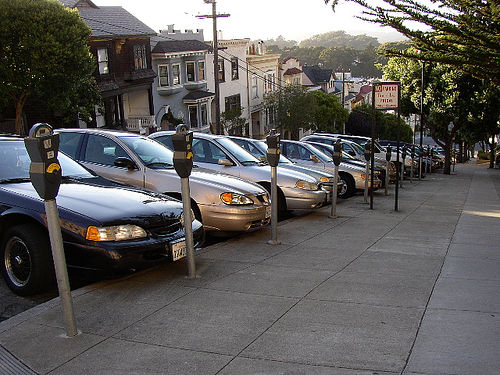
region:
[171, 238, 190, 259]
white licence plate on a black car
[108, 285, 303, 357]
concrete sidewalk square next to sidewalk square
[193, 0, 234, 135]
tall wooden utility pole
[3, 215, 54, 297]
black rubber tire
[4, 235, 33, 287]
chrome hubcap surrounded by tire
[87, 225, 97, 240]
yellow turn signal light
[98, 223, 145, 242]
white headlight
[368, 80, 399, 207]
white sign on metal pole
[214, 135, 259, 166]
windshield on front of car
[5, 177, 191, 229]
metal hood of car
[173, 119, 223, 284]
parking meter on sidewalk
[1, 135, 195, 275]
black car parked on street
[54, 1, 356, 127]
row of houses by street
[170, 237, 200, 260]
license plate on front of car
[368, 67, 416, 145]
no parking sign on sidewalk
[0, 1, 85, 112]
tree across the street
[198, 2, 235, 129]
light pole across the street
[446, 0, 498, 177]
row of trees down the sidewalk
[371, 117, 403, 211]
pole holding no parking sign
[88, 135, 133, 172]
passenger window of car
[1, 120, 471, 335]
A long row of parking meters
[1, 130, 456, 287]
A long row of parked cars in a parking lot.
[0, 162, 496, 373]
Cemented, clean sidewalk.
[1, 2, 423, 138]
A long row of houses behind the parked cars.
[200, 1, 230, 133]
Elecricity pole supporting overhead wires.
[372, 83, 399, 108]
A signboard on the sidewalk.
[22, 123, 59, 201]
A parking meter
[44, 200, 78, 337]
A metal pole on which a parking meter is mounted.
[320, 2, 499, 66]
A tree with long straight barnches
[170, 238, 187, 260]
Registration plate on a car.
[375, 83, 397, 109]
The red and white sign on the pole.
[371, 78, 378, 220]
The pole the red and white sign is mounted on.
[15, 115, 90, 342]
The meter on the left.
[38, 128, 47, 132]
The time display screen on the meter on the left.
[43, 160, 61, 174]
The yellow sticker on the meter on the left.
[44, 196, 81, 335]
The gray pole the meter on the left is mounted on.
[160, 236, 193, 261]
The license plate of the black car.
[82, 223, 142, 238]
The left headlight of the black car.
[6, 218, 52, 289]
The front tire of the black car.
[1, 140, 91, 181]
The front window of the black car.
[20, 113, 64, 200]
the meter is black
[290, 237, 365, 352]
the sidewalk is gray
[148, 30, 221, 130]
the building is blue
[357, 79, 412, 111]
the sign is square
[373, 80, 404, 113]
the sign is red and white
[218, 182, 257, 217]
the car has a headlight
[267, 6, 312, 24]
the sky is white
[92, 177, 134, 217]
the hood is shiney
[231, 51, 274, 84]
the wires are thick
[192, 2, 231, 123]
the pole is tall